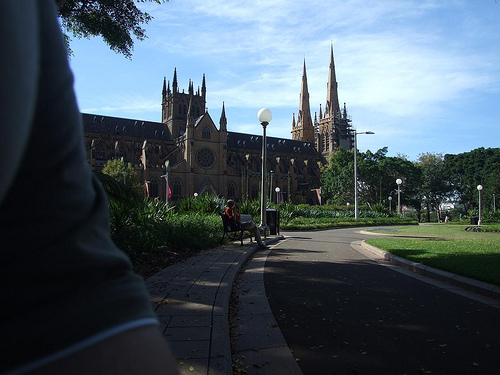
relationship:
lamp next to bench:
[255, 108, 273, 238] [211, 212, 263, 239]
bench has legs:
[223, 210, 262, 246] [227, 230, 263, 245]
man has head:
[218, 198, 272, 249] [224, 201, 236, 208]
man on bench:
[218, 198, 272, 249] [221, 213, 266, 245]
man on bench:
[218, 198, 272, 249] [224, 220, 259, 246]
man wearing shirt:
[218, 198, 272, 249] [223, 205, 240, 225]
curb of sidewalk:
[220, 243, 237, 373] [143, 238, 258, 373]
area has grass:
[363, 206, 484, 370] [418, 241, 484, 275]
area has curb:
[363, 206, 484, 370] [357, 233, 484, 328]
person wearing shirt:
[5, 3, 186, 373] [3, 2, 183, 372]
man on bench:
[218, 198, 272, 249] [224, 216, 261, 248]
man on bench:
[218, 198, 272, 249] [219, 215, 264, 253]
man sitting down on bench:
[218, 198, 272, 249] [220, 224, 268, 246]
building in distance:
[76, 40, 419, 201] [16, 46, 484, 176]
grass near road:
[398, 218, 484, 285] [289, 215, 484, 366]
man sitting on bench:
[218, 198, 272, 249] [217, 219, 262, 252]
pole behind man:
[252, 122, 278, 235] [219, 200, 270, 250]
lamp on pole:
[246, 100, 277, 122] [239, 76, 293, 276]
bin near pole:
[238, 193, 288, 268] [223, 79, 288, 322]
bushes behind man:
[4, 120, 261, 338] [214, 176, 258, 249]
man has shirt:
[213, 184, 256, 242] [204, 191, 261, 230]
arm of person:
[220, 199, 231, 239] [198, 195, 331, 284]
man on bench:
[218, 198, 272, 249] [173, 189, 288, 269]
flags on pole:
[124, 119, 171, 175] [158, 135, 183, 221]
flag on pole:
[300, 178, 354, 220] [312, 159, 360, 265]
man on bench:
[218, 198, 272, 249] [177, 172, 316, 282]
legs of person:
[248, 225, 291, 289] [205, 169, 335, 305]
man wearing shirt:
[218, 198, 272, 249] [216, 203, 250, 243]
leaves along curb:
[236, 250, 256, 368] [208, 236, 266, 371]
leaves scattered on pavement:
[228, 250, 255, 368] [230, 211, 490, 371]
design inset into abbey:
[194, 144, 215, 170] [191, 113, 225, 196]